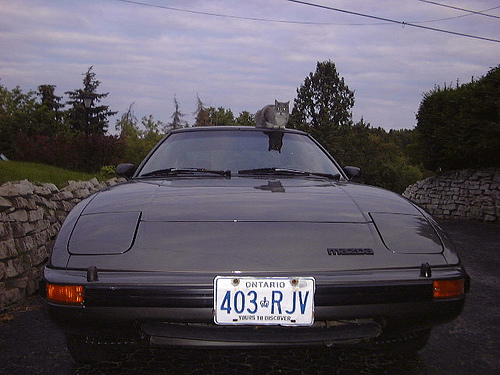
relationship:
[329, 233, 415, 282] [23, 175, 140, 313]
brand by headlights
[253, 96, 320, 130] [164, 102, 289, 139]
cat on roof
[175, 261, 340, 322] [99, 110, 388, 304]
license plate on car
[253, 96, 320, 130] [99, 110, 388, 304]
cat on car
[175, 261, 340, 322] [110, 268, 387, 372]
license plate on bumper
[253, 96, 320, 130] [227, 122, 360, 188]
cat on top